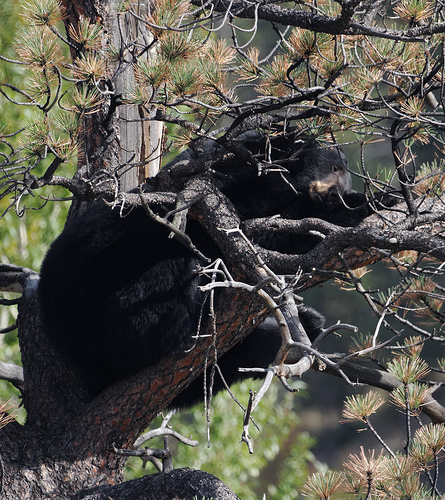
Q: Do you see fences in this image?
A: No, there are no fences.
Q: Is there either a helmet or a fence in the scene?
A: No, there are no fences or helmets.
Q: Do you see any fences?
A: No, there are no fences.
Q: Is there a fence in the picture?
A: No, there are no fences.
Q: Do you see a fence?
A: No, there are no fences.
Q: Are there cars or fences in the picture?
A: No, there are no fences or cars.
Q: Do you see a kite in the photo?
A: No, there are no kites.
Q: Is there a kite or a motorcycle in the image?
A: No, there are no kites or motorcycles.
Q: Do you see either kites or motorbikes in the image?
A: No, there are no kites or motorbikes.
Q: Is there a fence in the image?
A: No, there are no fences.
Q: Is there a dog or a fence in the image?
A: No, there are no fences or dogs.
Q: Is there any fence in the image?
A: No, there are no fences.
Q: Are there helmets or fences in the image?
A: No, there are no fences or helmets.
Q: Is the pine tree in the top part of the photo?
A: Yes, the pine tree is in the top of the image.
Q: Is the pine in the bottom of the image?
A: No, the pine is in the top of the image.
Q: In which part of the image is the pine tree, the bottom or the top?
A: The pine tree is in the top of the image.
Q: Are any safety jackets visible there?
A: No, there are no safety jackets.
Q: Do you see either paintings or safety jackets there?
A: No, there are no safety jackets or paintings.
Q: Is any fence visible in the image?
A: No, there are no fences.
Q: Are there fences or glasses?
A: No, there are no fences or glasses.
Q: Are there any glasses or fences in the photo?
A: No, there are no fences or glasses.